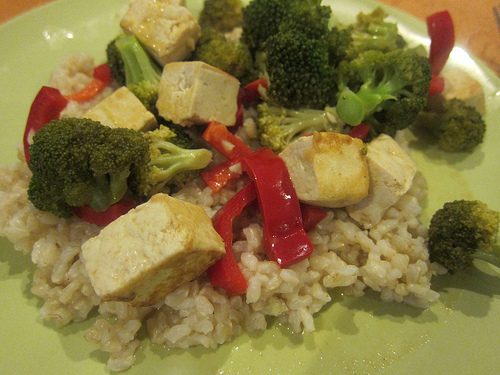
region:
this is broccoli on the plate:
[27, 112, 130, 205]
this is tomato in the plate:
[245, 151, 291, 246]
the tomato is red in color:
[255, 167, 292, 217]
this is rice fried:
[365, 196, 417, 280]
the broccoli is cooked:
[273, 46, 405, 119]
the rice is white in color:
[358, 217, 413, 277]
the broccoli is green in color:
[16, 121, 127, 206]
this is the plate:
[36, 7, 83, 44]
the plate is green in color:
[23, 6, 77, 48]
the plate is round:
[31, 7, 86, 47]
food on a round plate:
[6, 6, 493, 365]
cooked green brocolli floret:
[338, 48, 431, 138]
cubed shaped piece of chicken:
[78, 192, 226, 309]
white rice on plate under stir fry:
[6, 164, 459, 362]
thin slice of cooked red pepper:
[239, 146, 315, 267]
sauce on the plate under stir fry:
[254, 332, 422, 370]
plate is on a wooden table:
[3, 1, 498, 63]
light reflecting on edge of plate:
[446, 41, 498, 102]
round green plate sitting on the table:
[4, 3, 495, 371]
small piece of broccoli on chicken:
[358, 143, 370, 161]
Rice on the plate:
[66, 220, 438, 344]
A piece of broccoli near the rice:
[431, 190, 498, 256]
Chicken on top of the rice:
[96, 192, 208, 304]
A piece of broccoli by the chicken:
[31, 112, 211, 194]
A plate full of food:
[0, 0, 475, 373]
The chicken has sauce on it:
[126, 2, 194, 51]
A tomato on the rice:
[211, 143, 306, 274]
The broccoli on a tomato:
[39, 119, 212, 191]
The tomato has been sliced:
[204, 125, 315, 285]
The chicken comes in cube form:
[97, 189, 222, 295]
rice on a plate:
[15, 58, 499, 372]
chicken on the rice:
[62, 190, 227, 314]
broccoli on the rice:
[18, 102, 219, 215]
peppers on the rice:
[192, 127, 321, 303]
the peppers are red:
[199, 123, 325, 310]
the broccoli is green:
[24, 106, 222, 214]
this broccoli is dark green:
[243, 0, 431, 122]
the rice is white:
[5, 62, 460, 369]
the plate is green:
[0, 4, 492, 371]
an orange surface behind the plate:
[3, 2, 496, 95]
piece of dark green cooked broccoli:
[27, 116, 151, 218]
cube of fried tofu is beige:
[80, 192, 224, 306]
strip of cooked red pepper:
[202, 120, 314, 266]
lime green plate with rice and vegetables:
[0, 0, 499, 374]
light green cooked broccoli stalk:
[336, 69, 413, 126]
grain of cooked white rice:
[195, 295, 212, 316]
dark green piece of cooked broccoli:
[263, 28, 338, 109]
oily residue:
[107, 128, 473, 374]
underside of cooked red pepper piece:
[22, 85, 68, 167]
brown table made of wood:
[0, 0, 498, 78]